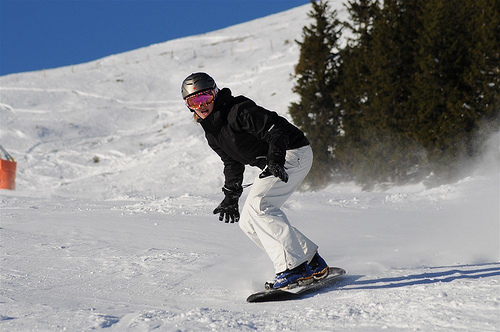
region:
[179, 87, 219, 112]
Purple tinted goggles on a snowboarder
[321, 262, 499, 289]
Shadow cast from the snowboarder.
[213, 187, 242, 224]
A right hand black glove.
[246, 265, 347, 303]
A black snowboard on a person in the snow.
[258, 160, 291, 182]
The left hand of a person snowboarding.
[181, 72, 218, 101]
Dark grey helmet on a snowboarder.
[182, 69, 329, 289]
A snowboarding woman in purple tinted goggles and white pants.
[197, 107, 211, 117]
Open mouth of a woman.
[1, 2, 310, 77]
A dark blue sky.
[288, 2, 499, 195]
Dark green group of trees.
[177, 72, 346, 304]
a lady skiing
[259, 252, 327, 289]
a pair of sneakers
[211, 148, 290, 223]
the black gloves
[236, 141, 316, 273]
pair of white pants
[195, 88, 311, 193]
a black jacket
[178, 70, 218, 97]
a grey helmet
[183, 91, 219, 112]
the bright goggles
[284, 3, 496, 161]
a bush on slope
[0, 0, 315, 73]
a clear blue sky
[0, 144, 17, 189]
an orange bucket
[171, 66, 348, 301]
a person snowboarding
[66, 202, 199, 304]
the snow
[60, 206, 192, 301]
the snow is white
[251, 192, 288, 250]
the pants are white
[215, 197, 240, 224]
the skier is wearing gloves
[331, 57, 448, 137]
the bush is green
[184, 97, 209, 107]
snow goggles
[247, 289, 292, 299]
a snowboard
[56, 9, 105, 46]
the sky is clear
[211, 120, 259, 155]
a black jacket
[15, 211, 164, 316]
The snow is the color white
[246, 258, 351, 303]
The snowboard on the ground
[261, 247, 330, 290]
The feet of the woman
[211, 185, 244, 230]
The woman is wearing a glove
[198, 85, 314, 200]
The woman has on a black jacket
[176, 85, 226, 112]
The woman is wearing snow goggles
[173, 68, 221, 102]
The woman is wearing a helmet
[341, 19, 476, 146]
The leaves on the tree are green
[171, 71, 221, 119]
The head of the woman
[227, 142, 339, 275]
The woman is wearing white pants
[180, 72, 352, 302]
a woman on a snow board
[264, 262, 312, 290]
boot on a snowboard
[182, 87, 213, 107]
goggles on a woman's face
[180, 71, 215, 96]
helmet on a woman's head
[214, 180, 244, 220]
glove on a woman's hand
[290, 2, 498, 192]
trees in the snow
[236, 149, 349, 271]
a person's white pants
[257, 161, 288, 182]
a glove on a woman's hand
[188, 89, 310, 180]
a black jacket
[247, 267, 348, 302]
a snowboard on snow